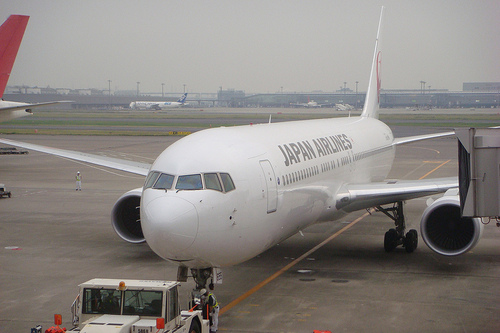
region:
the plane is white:
[167, 212, 184, 232]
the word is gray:
[309, 142, 344, 154]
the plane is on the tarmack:
[301, 185, 426, 280]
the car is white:
[95, 322, 113, 332]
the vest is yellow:
[213, 296, 219, 309]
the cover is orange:
[153, 315, 168, 331]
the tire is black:
[381, 226, 398, 249]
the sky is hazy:
[147, 31, 184, 52]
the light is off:
[48, 310, 68, 328]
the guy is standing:
[71, 167, 86, 194]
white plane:
[2, 32, 480, 259]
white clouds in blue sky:
[194, 13, 245, 48]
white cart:
[58, 255, 188, 330]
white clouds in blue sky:
[422, 26, 464, 47]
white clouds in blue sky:
[107, 12, 175, 49]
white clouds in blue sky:
[244, 21, 292, 51]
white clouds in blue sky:
[302, 3, 352, 41]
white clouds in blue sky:
[145, 15, 213, 53]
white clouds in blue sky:
[410, 28, 448, 55]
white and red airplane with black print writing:
[1, 25, 496, 289]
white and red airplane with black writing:
[5, 10, 480, 257]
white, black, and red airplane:
[20, 10, 495, 271]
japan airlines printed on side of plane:
[242, 107, 374, 173]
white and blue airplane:
[77, 66, 203, 121]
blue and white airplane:
[128, 79, 222, 138]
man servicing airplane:
[191, 272, 229, 329]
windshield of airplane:
[124, 135, 236, 199]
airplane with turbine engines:
[38, 46, 487, 272]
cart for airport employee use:
[56, 258, 248, 324]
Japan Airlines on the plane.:
[265, 133, 366, 168]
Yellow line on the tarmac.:
[215, 136, 450, 316]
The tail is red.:
[0, 13, 36, 102]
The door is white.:
[250, 153, 290, 222]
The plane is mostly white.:
[0, 3, 461, 280]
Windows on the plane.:
[276, 144, 368, 189]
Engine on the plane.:
[413, 185, 485, 260]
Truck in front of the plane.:
[54, 265, 220, 332]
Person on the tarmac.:
[66, 163, 96, 198]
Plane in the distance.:
[120, 93, 192, 113]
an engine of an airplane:
[417, 182, 484, 263]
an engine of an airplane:
[105, 189, 146, 249]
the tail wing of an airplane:
[377, 124, 457, 156]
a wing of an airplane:
[3, 131, 151, 182]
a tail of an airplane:
[355, 7, 387, 121]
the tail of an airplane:
[1, 12, 33, 101]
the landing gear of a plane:
[374, 204, 419, 260]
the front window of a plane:
[141, 167, 236, 192]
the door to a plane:
[253, 151, 279, 216]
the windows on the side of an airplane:
[279, 162, 344, 187]